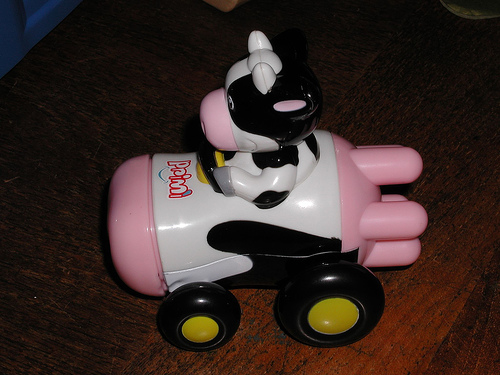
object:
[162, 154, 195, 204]
writing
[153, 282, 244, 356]
tire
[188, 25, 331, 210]
cow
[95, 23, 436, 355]
car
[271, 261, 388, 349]
tire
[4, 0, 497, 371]
surface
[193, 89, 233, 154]
cow's nose